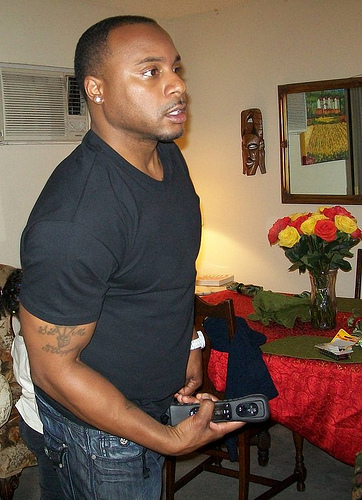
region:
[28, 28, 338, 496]
a man standing up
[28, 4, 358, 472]
a man holding a wii remote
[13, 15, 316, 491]
a man holding a black wii remote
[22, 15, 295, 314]
a man wearing an earring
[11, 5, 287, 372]
a man wearing a shirt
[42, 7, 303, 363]
a man wearing a black shirt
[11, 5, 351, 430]
a man with a tatto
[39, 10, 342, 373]
a man with tattoo on his arm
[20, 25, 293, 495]
a man wearing jeans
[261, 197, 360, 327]
red and yellow flowers in a vase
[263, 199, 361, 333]
colorful bouquet of roses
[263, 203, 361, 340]
roses in glass vase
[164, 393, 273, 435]
black wii remote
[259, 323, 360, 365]
green placemat with batteries on top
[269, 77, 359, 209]
small rectangular mirror with wooden frame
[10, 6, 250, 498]
man playing Wii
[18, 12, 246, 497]
man wearing denim jeans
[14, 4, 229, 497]
man wearing black tshirt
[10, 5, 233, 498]
man with tattoo on right arm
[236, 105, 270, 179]
a mask on the wall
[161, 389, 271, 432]
HE holds a remote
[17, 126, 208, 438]
The man wears a black shirt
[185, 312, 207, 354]
A white wrist watch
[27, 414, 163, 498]
A pair of jeans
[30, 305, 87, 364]
Tattoo on the bicep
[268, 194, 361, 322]
Flowers in the vase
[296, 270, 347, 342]
The vase on the table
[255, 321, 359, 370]
Green mat on the table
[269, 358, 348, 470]
The red table cloth hanging from the table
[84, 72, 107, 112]
The man has an earing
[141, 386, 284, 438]
The man is playing Wii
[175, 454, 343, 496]
The flooring is dark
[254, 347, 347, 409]
The table cloth is red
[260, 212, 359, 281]
The flowers are in the vase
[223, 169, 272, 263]
The wall is light colored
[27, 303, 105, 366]
The man has a tattoo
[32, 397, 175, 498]
The man has jeans on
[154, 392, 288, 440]
The Wii remote is black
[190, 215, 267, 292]
The light is on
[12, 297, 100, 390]
man has tattoo on arm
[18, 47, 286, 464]
man playing video games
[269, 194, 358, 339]
flowers and vase on table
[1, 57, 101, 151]
wall air conditioner unit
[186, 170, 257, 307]
artificial light is on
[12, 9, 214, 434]
man wearing black t-shirt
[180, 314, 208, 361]
man wearing white wristwatch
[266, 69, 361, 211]
mirror hanging on wall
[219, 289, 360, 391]
table covered with red table cloth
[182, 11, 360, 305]
walls are light colored